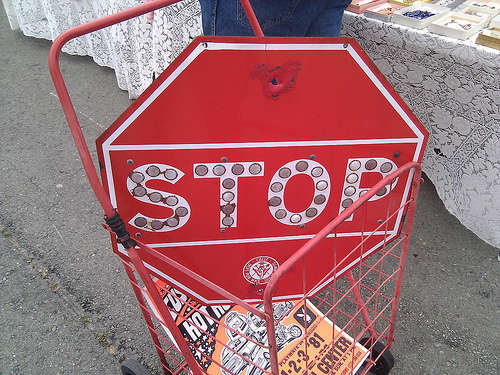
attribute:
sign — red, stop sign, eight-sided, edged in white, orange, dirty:
[93, 36, 430, 306]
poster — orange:
[141, 276, 371, 374]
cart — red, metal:
[50, 1, 426, 374]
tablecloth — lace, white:
[2, 0, 206, 100]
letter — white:
[126, 164, 192, 234]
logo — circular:
[243, 254, 279, 287]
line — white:
[106, 137, 419, 152]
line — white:
[133, 231, 394, 246]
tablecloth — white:
[342, 11, 500, 250]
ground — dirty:
[1, 32, 499, 374]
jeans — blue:
[197, 1, 352, 38]